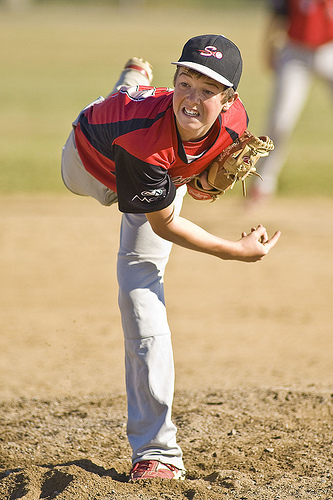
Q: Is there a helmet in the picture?
A: No, there are no helmets.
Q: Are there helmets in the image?
A: No, there are no helmets.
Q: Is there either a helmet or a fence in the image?
A: No, there are no helmets or fences.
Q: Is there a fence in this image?
A: No, there are no fences.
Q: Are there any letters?
A: Yes, there are letters.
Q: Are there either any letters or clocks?
A: Yes, there are letters.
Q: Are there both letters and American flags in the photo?
A: No, there are letters but no American flags.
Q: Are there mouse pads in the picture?
A: No, there are no mouse pads.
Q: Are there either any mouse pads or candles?
A: No, there are no mouse pads or candles.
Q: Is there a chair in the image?
A: No, there are no chairs.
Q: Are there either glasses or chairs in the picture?
A: No, there are no chairs or glasses.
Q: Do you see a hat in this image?
A: Yes, there is a hat.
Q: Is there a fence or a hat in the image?
A: Yes, there is a hat.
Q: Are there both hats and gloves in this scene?
A: Yes, there are both a hat and gloves.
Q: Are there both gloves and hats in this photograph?
A: Yes, there are both a hat and gloves.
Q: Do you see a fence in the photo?
A: No, there are no fences.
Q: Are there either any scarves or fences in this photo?
A: No, there are no fences or scarves.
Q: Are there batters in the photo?
A: No, there are no batters.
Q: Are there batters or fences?
A: No, there are no batters or fences.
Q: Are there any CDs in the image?
A: No, there are no cds.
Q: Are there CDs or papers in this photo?
A: No, there are no CDs or papers.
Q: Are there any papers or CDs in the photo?
A: No, there are no CDs or papers.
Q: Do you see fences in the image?
A: No, there are no fences.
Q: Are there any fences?
A: No, there are no fences.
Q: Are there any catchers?
A: No, there are no catchers.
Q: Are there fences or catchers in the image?
A: No, there are no catchers or fences.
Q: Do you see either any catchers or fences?
A: No, there are no catchers or fences.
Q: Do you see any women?
A: No, there are no women.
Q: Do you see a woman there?
A: No, there are no women.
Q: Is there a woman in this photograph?
A: No, there are no women.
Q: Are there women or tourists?
A: No, there are no women or tourists.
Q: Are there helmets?
A: No, there are no helmets.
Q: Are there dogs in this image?
A: No, there are no dogs.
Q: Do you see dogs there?
A: No, there are no dogs.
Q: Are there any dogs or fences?
A: No, there are no dogs or fences.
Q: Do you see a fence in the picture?
A: No, there are no fences.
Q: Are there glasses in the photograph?
A: No, there are no glasses.